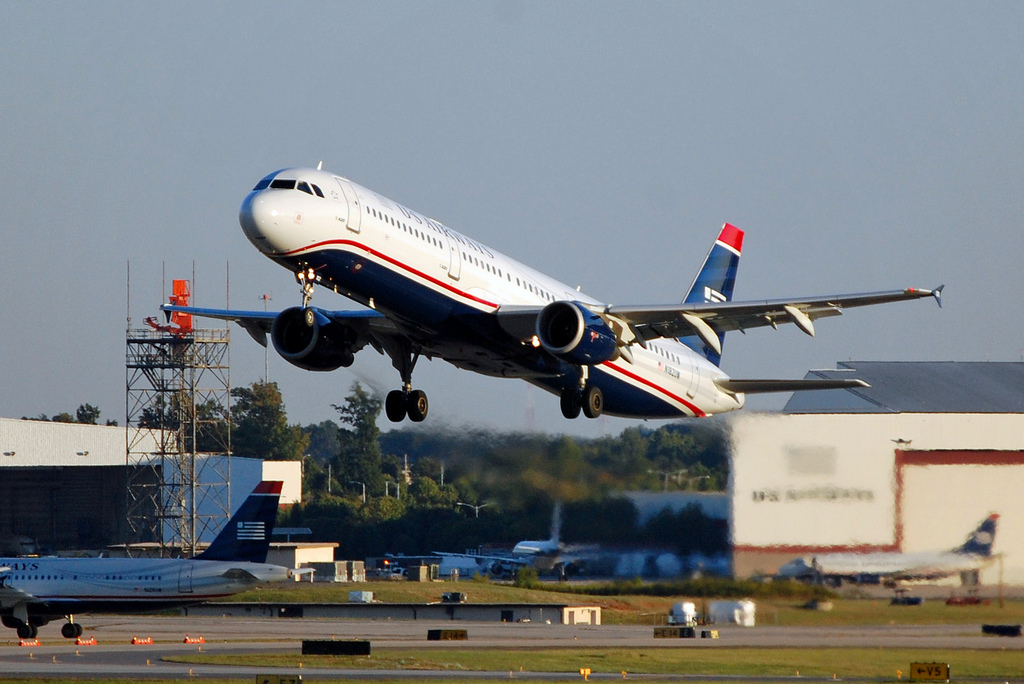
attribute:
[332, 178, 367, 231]
doors — closed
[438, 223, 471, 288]
doors — closed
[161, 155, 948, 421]
plane — taking off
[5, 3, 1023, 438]
sky — gray, blue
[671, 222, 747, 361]
tail — blue, red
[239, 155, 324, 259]
nose — white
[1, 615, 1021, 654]
runway — dark gray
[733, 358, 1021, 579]
building — white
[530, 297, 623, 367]
engine — dark blue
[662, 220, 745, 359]
tail — red, blue